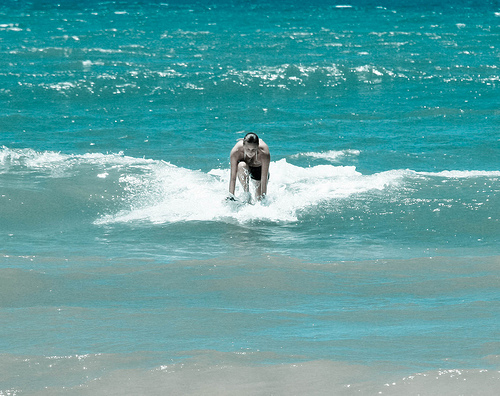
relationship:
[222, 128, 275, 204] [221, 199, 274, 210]
girl on surfboard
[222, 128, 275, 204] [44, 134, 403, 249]
girl on wave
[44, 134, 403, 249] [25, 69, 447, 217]
wave in water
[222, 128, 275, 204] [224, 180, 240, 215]
girl has hands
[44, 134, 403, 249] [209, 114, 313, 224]
wave by girl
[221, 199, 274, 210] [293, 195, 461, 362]
surfboard on ocean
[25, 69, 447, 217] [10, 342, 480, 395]
water meeting beach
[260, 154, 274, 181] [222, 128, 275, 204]
bicep of girl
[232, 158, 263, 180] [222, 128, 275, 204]
knee of girl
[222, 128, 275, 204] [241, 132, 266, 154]
girl has face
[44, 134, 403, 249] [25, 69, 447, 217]
wave on water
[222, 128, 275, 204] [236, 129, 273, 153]
girl has head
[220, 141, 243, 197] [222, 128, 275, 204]
arm of girl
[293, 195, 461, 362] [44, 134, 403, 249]
ocean has wave